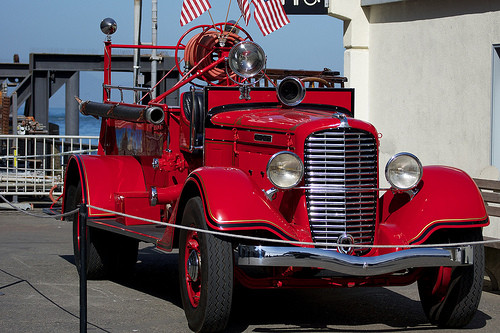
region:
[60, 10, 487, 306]
this is a vintage truck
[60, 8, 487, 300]
a vintage fire truck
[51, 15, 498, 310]
this is an old fashioned fire truck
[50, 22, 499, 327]
the truck is bright red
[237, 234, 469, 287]
a chrome bumper on the truck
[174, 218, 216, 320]
the wheels are red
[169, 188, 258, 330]
the tire is black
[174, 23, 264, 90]
the hose is wrapped in this wheel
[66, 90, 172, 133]
this hose connects to a hydrant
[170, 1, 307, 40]
there are three American flags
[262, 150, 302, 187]
a circular car headlight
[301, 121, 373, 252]
the front grille of an old car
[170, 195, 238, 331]
a thin rubber tire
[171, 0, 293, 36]
a pair of american flags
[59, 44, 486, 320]
an old red car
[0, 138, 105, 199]
a white fence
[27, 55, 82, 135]
the metal pillars of a dock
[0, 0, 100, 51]
a clear blue sky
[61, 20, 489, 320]
an antique red car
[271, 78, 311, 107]
a horn on an old car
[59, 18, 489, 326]
an antique fire engine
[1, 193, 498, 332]
rope strung on black pole around fire engine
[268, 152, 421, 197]
headlights on fire engine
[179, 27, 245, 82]
hose on a spool on fire enguine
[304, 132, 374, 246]
silver grill on fire engine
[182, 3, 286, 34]
American flags on engine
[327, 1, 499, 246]
white building next to fire engine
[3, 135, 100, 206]
a white metal fence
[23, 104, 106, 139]
blue ocean water behind gray beams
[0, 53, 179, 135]
gray beam structure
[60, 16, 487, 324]
the truck is parked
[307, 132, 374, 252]
grill on the front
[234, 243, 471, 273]
the bumper is chrome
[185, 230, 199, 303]
hub cap is red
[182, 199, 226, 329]
the tire is black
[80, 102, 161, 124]
metal tube on side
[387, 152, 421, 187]
headlight on the front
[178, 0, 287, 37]
a couple of flags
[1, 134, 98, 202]
gate made of metal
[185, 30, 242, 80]
the hose is orange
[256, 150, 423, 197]
Front of car headlights.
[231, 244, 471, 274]
Chrome metal bar on front.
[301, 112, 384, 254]
Chrome metal antique grill.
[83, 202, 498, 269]
Small wire protecting vehicle.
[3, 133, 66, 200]
white metal security gate.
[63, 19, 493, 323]
Red antique fire truck.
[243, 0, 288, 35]
Part of the American flag.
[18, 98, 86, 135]
Blue ocean in the background.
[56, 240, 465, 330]
Shadow under the vehicle.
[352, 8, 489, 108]
Beige building on the right.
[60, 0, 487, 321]
flags on an old red firetruck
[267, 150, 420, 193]
2 old round headlights on the firetruck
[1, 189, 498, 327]
wire fence to keep spectating at a distance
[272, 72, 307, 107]
horn on the firetruck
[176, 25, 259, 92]
hose for fire on the firetruck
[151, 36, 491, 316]
front of the car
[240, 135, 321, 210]
light on front of car